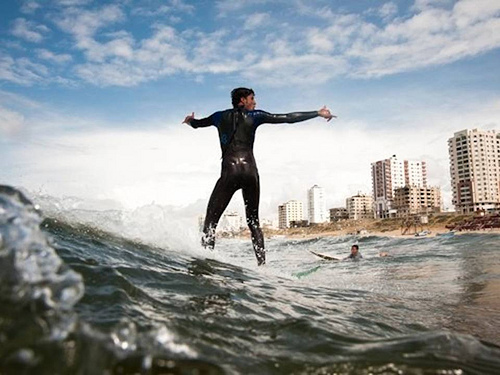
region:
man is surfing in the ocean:
[128, 57, 343, 287]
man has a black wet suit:
[203, 106, 281, 267]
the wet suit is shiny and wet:
[185, 105, 290, 265]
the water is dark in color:
[5, 195, 467, 372]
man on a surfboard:
[295, 242, 411, 262]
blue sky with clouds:
[6, 10, 489, 81]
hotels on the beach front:
[276, 128, 493, 209]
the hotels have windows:
[460, 138, 496, 175]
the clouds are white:
[331, 5, 489, 57]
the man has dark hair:
[225, 69, 252, 110]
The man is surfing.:
[184, 61, 351, 281]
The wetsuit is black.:
[208, 100, 265, 226]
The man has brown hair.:
[225, 79, 256, 111]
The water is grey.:
[103, 266, 250, 356]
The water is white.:
[117, 189, 203, 253]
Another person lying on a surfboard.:
[296, 235, 394, 275]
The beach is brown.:
[304, 220, 368, 235]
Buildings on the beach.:
[305, 131, 497, 226]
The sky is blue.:
[11, 10, 116, 97]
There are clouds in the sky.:
[332, 3, 498, 76]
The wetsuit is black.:
[218, 135, 270, 195]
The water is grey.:
[127, 264, 219, 336]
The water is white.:
[84, 192, 193, 243]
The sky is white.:
[49, 130, 216, 197]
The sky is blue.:
[2, 3, 49, 50]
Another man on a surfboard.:
[307, 237, 395, 271]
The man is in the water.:
[336, 227, 386, 262]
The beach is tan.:
[301, 220, 391, 237]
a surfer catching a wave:
[15, 78, 332, 369]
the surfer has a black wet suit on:
[180, 85, 335, 270]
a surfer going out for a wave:
[302, 240, 382, 265]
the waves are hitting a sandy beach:
[227, 213, 497, 243]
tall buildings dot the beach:
[221, 125, 496, 236]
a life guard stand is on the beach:
[397, 210, 429, 238]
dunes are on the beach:
[287, 210, 497, 238]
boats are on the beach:
[411, 226, 456, 237]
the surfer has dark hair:
[227, 85, 257, 111]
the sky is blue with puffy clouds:
[13, 1, 499, 220]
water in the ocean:
[1, 182, 497, 374]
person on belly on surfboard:
[306, 242, 393, 262]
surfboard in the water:
[308, 247, 341, 265]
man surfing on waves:
[173, 81, 337, 272]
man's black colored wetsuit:
[186, 105, 318, 262]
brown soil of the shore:
[205, 210, 499, 247]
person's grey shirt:
[345, 248, 364, 259]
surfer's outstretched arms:
[176, 107, 341, 128]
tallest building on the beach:
[446, 122, 498, 221]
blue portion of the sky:
[1, 0, 499, 136]